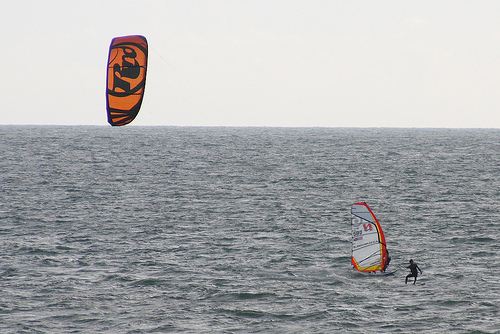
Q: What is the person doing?
A: Kitesurfing.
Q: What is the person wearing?
A: Wetsuit.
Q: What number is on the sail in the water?
A: 12.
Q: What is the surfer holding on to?
A: Ropes from the sail.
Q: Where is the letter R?
A: On the kite.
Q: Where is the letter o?
A: On the kite.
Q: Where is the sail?
A: On the board.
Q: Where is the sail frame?
A: On the sail.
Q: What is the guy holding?
A: A windsurf.